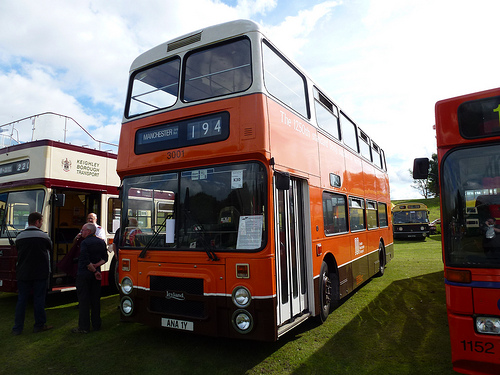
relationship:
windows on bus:
[321, 188, 396, 237] [116, 19, 394, 341]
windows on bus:
[260, 36, 394, 171] [116, 19, 394, 341]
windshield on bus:
[118, 161, 267, 251] [116, 19, 394, 341]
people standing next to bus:
[12, 210, 109, 335] [116, 19, 394, 341]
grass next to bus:
[275, 231, 444, 374] [116, 19, 394, 341]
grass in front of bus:
[2, 298, 283, 373] [116, 19, 394, 341]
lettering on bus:
[279, 111, 363, 165] [116, 19, 394, 341]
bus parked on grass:
[116, 19, 394, 341] [275, 231, 444, 374]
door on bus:
[273, 169, 314, 328] [116, 19, 394, 341]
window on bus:
[181, 35, 253, 103] [116, 19, 394, 341]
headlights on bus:
[230, 285, 253, 333] [116, 19, 394, 341]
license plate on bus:
[161, 316, 194, 331] [116, 19, 394, 341]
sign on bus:
[137, 125, 180, 145] [116, 19, 394, 341]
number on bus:
[186, 117, 222, 140] [116, 19, 394, 341]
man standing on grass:
[76, 222, 109, 334] [2, 298, 283, 373]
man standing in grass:
[15, 212, 55, 335] [2, 298, 283, 373]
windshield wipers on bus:
[138, 193, 218, 263] [116, 19, 394, 341]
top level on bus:
[115, 17, 392, 194] [116, 19, 394, 341]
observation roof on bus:
[1, 109, 122, 157] [0, 111, 121, 299]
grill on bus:
[150, 274, 202, 316] [116, 19, 394, 341]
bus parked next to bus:
[116, 19, 394, 341] [413, 86, 499, 374]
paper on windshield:
[235, 213, 264, 249] [118, 161, 267, 251]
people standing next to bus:
[12, 210, 109, 335] [0, 111, 121, 299]